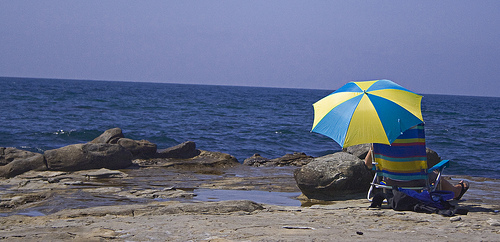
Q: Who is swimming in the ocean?
A: No one.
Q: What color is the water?
A: Blue.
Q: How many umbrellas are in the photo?
A: One.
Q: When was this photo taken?
A: Daytime.